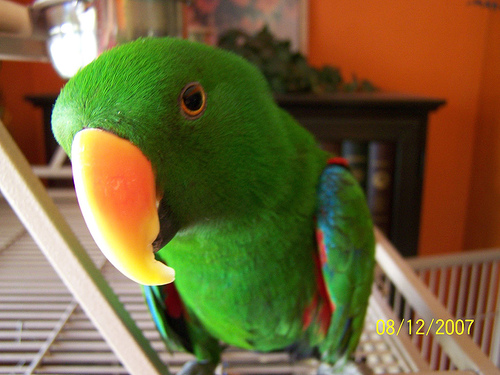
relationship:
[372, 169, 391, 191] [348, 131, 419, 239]
symbol on book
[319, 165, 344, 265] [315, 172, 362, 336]
blue patch on feather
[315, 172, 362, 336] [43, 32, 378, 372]
feather of bird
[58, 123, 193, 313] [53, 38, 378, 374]
beak of parrot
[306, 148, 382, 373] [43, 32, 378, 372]
wing of bird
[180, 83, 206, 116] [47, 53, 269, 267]
eye of bird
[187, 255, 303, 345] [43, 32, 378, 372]
stomach of bird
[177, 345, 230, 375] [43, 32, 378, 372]
feet of bird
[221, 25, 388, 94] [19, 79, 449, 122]
plant on top shelf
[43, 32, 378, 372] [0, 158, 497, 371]
bird on top of cage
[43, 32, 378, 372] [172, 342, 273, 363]
bird using feet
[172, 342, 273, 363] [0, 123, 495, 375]
feet using bird cage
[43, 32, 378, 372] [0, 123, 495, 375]
bird standing bird cage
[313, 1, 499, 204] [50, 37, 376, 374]
wall behind bird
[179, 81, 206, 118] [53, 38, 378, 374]
eye on parrot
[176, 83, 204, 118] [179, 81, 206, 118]
yellow circle in eye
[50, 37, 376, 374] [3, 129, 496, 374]
bird in bird cage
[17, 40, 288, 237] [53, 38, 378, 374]
head on parrot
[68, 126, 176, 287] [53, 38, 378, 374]
beak on parrot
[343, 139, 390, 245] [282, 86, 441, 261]
book in bookcase